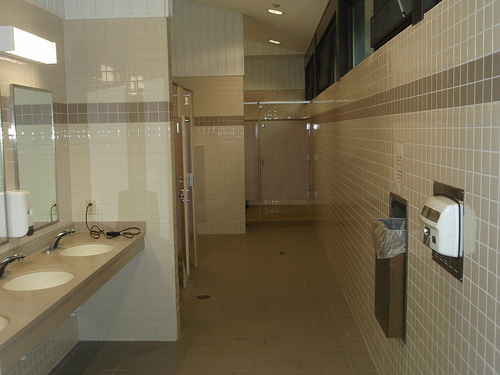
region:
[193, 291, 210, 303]
round floor drain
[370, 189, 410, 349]
stainless steel waste receptacle with plastic bag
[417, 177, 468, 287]
White recessed hand drying blower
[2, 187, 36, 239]
white plastic soap dispenser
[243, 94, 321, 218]
Clouded shower stall door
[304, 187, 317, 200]
Hinge for shower stall door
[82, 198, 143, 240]
Electrical outlet with black cord plugged in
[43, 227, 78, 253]
Chrome colored bathroom faucet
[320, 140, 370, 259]
four inch tiled wall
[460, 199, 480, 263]
Image of electric hand dryer reflected on tile wall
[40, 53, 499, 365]
a public bathroom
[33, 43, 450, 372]
a clean public bathroom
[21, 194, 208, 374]
a bathroom with sinks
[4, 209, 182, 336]
a bathroom with a counter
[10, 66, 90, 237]
a bathroom with mirrors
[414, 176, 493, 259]
a bathroom with hand dryer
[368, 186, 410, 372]
a bathroom with garbage can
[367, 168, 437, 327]
a bathroom with trash can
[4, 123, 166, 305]
a bathroom with multiple sinks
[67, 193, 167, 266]
a cord plugged into the wall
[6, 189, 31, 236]
white roll of paper towels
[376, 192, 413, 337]
garbage can attached to wall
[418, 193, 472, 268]
white metal hand dryer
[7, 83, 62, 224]
tall bathroom mirror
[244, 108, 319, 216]
bathroom stall door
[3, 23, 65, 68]
fluorescent bathroom light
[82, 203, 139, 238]
black electrical cord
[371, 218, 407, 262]
plastic garbage bag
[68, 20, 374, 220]
glossy light tan and cream bathroom tile walls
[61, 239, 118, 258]
white round bathroom sink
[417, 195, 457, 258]
Hot air hand dryer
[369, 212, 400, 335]
Brown trash can with plastic bag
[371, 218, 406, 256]
Plastic bag in trash can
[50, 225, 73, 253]
Silver faucet for sink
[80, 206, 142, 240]
Black cord for electronics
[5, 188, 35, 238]
White soap dispenser over sinks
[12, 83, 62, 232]
Mirror on wall behind sinks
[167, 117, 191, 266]
Tan bathroom stall door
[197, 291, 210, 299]
Silver drain in bathroom floor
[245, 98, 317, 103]
Silver support pipe above stall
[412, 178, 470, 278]
White hand dryer on bathroom wall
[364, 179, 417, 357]
Silver trash can with liner on wall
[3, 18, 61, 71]
Light on bathroom wall above sink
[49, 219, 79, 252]
Silver faucet on bathroom sink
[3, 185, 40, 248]
White soap despenser in bathroom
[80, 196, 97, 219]
Power outlet on bathroom wall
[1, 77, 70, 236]
Bathroom mirror above a sink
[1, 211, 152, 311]
Two sinks in a public rest room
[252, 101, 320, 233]
Bathroom stall door in restroom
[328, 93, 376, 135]
Tan and brown tile on bathroom wall